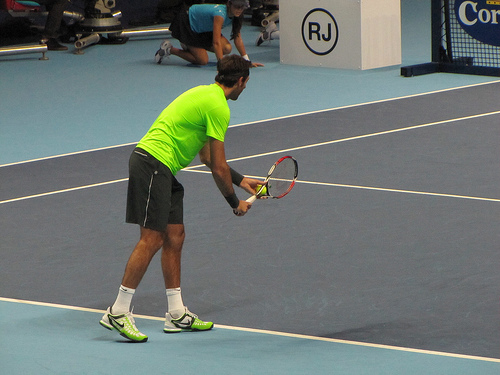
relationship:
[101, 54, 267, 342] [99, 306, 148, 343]
tennis player wears shoe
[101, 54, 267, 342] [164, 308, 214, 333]
tennis player wears shoe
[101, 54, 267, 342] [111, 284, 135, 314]
tennis player wears sock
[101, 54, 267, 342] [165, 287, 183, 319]
tennis player wears sock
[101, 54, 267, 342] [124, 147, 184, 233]
tennis player wears shorts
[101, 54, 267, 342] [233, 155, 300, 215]
tennis player holding tennis racket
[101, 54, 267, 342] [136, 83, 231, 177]
tennis player wearing shirt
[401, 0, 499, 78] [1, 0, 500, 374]
net on tennis court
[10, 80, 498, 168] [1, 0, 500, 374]
baseline painted on tennis court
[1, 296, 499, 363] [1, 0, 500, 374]
baseline painted on tennis court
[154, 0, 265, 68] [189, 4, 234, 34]
ball girl wearing t-shirt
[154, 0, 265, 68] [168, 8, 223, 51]
ball girl wearing skirt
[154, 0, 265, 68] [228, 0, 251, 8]
ball girl wearing cap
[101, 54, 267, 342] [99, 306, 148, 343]
tennis player wearing shoe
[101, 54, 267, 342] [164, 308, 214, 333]
tennis player wearing shoe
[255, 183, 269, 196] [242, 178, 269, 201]
tennis ball held in hand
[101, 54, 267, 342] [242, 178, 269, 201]
tennis player has hand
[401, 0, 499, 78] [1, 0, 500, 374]
net across tennis court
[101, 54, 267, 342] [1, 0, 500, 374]
tennis player standing on tennis court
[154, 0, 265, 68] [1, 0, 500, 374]
ball girl kneeling on tennis court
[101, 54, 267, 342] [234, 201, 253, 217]
tennis player has hand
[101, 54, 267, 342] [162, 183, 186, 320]
tennis player has leg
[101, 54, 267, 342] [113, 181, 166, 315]
tennis player has leg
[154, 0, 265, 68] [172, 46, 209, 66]
ball girl has leg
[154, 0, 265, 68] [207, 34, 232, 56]
ball girl has leg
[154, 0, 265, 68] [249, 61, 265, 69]
ball girl has hand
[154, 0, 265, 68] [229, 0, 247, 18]
ball girl has head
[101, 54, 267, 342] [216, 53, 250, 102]
tennis player has head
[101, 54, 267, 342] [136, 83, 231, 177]
tennis player wears shirt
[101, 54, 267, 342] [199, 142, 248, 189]
tennis player has arm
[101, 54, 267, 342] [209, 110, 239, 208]
tennis player has arm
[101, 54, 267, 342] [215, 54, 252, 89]
tennis player has hair